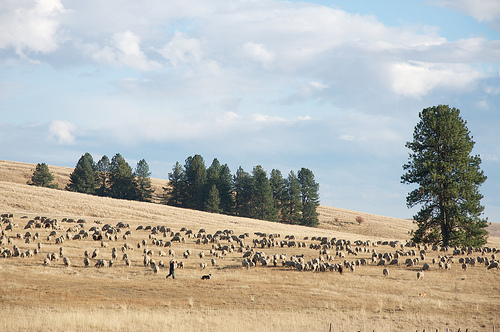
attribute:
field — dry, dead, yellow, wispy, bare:
[1, 219, 497, 330]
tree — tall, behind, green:
[404, 106, 491, 248]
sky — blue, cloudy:
[0, 1, 498, 222]